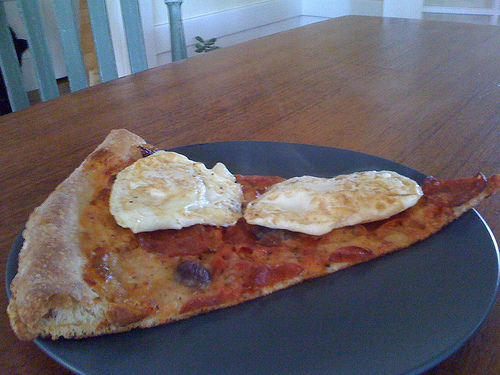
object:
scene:
[0, 0, 500, 375]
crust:
[6, 126, 129, 345]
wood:
[311, 25, 479, 123]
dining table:
[0, 14, 500, 373]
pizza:
[6, 128, 498, 341]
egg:
[243, 169, 423, 235]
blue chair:
[4, 0, 185, 110]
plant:
[193, 36, 220, 53]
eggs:
[107, 150, 244, 235]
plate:
[3, 139, 498, 374]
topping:
[175, 260, 210, 287]